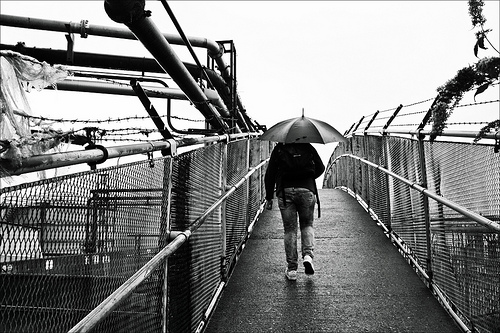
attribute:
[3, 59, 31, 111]
plastic — ripped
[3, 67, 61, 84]
plastic — ripped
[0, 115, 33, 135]
plastic — ripped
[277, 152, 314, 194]
jacket — black 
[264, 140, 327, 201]
sweater — black 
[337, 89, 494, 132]
barbed wire — barbed 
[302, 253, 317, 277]
shoe — white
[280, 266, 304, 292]
white shoe — white 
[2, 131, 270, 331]
fence — chain link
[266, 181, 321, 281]
black jeans — black 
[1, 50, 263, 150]
barbed wire — barbed 